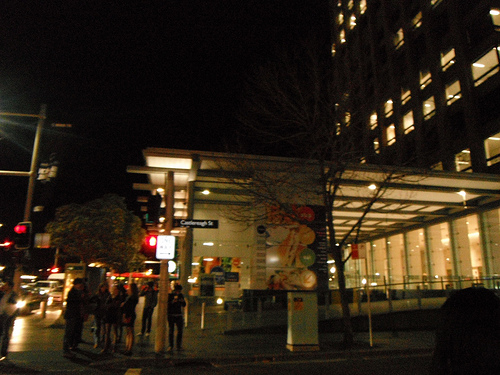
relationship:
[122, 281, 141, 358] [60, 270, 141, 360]
person in group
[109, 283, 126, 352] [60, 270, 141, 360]
person in group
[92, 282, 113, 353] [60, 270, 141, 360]
person in group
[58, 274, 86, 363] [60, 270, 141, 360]
person in group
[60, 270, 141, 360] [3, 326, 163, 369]
group standing on street corner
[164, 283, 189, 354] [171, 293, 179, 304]
woman holding cup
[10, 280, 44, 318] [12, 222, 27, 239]
car waiting at stop light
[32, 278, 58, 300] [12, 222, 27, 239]
car waiting at stop light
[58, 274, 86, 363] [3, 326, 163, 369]
person on street corner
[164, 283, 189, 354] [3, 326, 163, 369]
person on street corner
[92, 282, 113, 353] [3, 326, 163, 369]
person on street corner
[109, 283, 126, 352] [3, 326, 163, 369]
person on street corner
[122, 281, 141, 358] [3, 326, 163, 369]
person on street corner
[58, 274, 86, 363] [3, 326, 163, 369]
person standing at street corner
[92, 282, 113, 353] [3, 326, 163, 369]
person standing at street corner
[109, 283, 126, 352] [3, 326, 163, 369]
person standing at street corner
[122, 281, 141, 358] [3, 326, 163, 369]
person standing at street corner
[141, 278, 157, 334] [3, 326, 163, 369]
person standing at street corner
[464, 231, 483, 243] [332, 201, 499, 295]
light in a lobby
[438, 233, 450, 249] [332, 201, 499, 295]
light in a lobby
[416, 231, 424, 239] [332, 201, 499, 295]
light in a lobby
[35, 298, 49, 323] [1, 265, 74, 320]
trash can on street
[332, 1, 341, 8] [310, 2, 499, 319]
upper window of building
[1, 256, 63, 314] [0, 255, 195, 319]
traffic in distance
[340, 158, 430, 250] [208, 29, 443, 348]
branch of tree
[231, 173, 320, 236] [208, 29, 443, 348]
branch of tree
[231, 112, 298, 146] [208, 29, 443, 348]
branch of tree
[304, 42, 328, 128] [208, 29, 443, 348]
branch of tree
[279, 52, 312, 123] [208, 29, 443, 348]
branch of tree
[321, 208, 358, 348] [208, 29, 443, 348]
trunk of tree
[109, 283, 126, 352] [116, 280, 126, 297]
person has hair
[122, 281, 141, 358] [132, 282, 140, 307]
person has hair